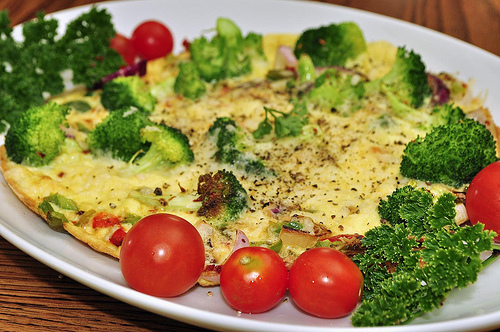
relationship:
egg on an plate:
[0, 33, 497, 288] [3, 2, 498, 330]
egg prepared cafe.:
[0, 33, 497, 288] [9, 10, 483, 329]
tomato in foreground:
[287, 246, 365, 318] [1, 212, 498, 330]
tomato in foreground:
[220, 246, 290, 314] [1, 212, 498, 330]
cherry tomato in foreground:
[121, 213, 203, 296] [1, 212, 498, 330]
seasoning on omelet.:
[283, 138, 340, 192] [306, 168, 356, 216]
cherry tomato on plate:
[121, 213, 203, 296] [3, 2, 498, 330]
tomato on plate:
[220, 246, 290, 314] [3, 2, 498, 330]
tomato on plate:
[287, 246, 365, 318] [3, 2, 498, 330]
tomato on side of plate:
[463, 157, 497, 244] [3, 2, 498, 330]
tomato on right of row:
[287, 243, 366, 318] [118, 214, 363, 319]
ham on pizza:
[94, 76, 369, 251] [4, 22, 499, 257]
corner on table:
[327, 0, 499, 62] [0, 0, 499, 328]